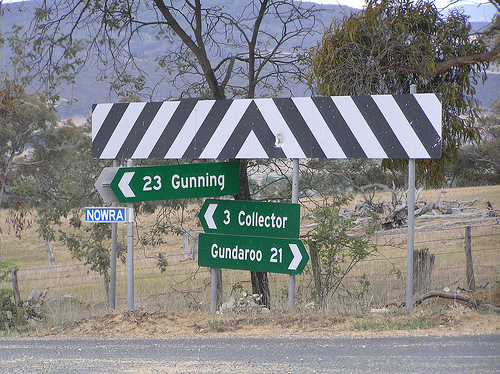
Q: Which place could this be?
A: It is a field.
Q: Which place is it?
A: It is a field.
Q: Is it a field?
A: Yes, it is a field.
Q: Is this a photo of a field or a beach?
A: It is showing a field.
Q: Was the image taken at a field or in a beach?
A: It was taken at a field.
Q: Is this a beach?
A: No, it is a field.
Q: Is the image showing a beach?
A: No, the picture is showing a field.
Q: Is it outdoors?
A: Yes, it is outdoors.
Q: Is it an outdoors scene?
A: Yes, it is outdoors.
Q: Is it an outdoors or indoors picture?
A: It is outdoors.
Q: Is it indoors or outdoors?
A: It is outdoors.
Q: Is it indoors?
A: No, it is outdoors.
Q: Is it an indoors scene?
A: No, it is outdoors.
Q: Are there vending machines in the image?
A: No, there are no vending machines.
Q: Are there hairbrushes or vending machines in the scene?
A: No, there are no vending machines or hairbrushes.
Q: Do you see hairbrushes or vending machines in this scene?
A: No, there are no vending machines or hairbrushes.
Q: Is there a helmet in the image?
A: No, there are no helmets.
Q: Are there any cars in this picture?
A: No, there are no cars.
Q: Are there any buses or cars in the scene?
A: No, there are no cars or buses.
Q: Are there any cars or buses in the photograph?
A: No, there are no cars or buses.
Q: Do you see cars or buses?
A: No, there are no cars or buses.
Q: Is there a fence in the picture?
A: Yes, there is a fence.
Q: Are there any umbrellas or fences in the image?
A: Yes, there is a fence.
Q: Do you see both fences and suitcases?
A: No, there is a fence but no suitcases.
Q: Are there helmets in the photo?
A: No, there are no helmets.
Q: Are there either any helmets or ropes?
A: No, there are no helmets or ropes.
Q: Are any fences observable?
A: Yes, there is a fence.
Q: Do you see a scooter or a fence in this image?
A: Yes, there is a fence.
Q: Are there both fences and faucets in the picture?
A: No, there is a fence but no faucets.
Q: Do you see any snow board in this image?
A: No, there are no snowboards.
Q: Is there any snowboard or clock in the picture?
A: No, there are no snowboards or clocks.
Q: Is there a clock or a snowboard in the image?
A: No, there are no snowboards or clocks.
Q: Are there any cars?
A: No, there are no cars.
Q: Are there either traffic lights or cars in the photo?
A: No, there are no cars or traffic lights.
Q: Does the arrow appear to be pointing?
A: Yes, the arrow is pointing.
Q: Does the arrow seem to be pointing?
A: Yes, the arrow is pointing.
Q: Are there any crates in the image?
A: No, there are no crates.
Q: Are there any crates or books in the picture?
A: No, there are no crates or books.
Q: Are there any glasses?
A: No, there are no glasses.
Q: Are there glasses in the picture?
A: No, there are no glasses.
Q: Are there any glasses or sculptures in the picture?
A: No, there are no glasses or sculptures.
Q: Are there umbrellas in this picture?
A: No, there are no umbrellas.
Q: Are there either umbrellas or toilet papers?
A: No, there are no umbrellas or toilet papers.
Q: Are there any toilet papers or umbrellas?
A: No, there are no umbrellas or toilet papers.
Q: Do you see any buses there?
A: No, there are no buses.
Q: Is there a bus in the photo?
A: No, there are no buses.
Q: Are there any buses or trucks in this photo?
A: No, there are no buses or trucks.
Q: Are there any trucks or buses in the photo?
A: No, there are no buses or trucks.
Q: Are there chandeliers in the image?
A: No, there are no chandeliers.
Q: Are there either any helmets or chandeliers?
A: No, there are no chandeliers or helmets.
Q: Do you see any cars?
A: No, there are no cars.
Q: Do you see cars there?
A: No, there are no cars.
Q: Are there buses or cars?
A: No, there are no cars or buses.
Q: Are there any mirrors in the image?
A: No, there are no mirrors.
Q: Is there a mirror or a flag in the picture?
A: No, there are no mirrors or flags.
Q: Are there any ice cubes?
A: No, there are no ice cubes.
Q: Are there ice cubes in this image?
A: No, there are no ice cubes.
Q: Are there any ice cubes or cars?
A: No, there are no ice cubes or cars.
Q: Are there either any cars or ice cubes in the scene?
A: No, there are no ice cubes or cars.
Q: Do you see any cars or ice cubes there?
A: No, there are no ice cubes or cars.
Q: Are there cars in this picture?
A: No, there are no cars.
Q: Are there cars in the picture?
A: No, there are no cars.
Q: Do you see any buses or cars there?
A: No, there are no cars or buses.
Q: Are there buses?
A: No, there are no buses.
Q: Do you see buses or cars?
A: No, there are no buses or cars.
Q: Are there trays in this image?
A: No, there are no trays.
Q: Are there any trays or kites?
A: No, there are no trays or kites.